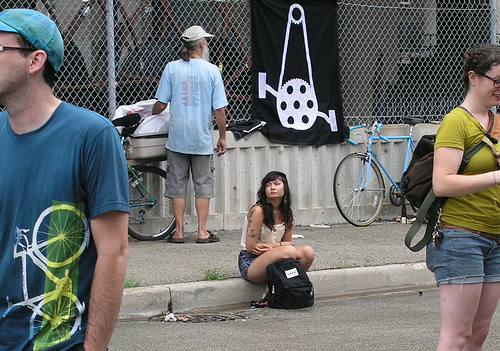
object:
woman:
[235, 169, 316, 309]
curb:
[116, 259, 441, 327]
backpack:
[264, 256, 314, 309]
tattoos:
[246, 208, 259, 238]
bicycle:
[330, 113, 437, 228]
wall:
[114, 119, 442, 239]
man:
[2, 3, 133, 350]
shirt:
[2, 99, 130, 348]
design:
[2, 199, 92, 349]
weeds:
[125, 270, 145, 288]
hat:
[0, 6, 67, 77]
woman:
[422, 44, 499, 349]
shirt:
[432, 106, 500, 240]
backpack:
[399, 109, 500, 252]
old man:
[149, 23, 230, 245]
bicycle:
[110, 112, 178, 241]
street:
[106, 286, 499, 350]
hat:
[182, 25, 215, 42]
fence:
[1, 2, 497, 132]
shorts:
[425, 225, 499, 289]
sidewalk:
[124, 214, 433, 292]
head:
[0, 7, 66, 98]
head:
[179, 24, 215, 59]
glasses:
[476, 70, 500, 88]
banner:
[248, 3, 348, 147]